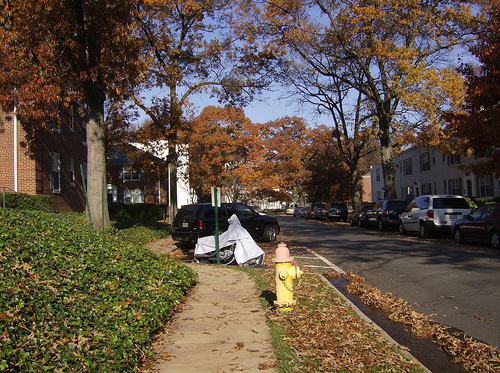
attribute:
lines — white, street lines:
[287, 235, 347, 273]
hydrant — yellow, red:
[265, 235, 311, 316]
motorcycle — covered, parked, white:
[187, 209, 274, 271]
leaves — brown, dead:
[339, 266, 499, 369]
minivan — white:
[394, 187, 477, 239]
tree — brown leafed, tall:
[5, 2, 153, 234]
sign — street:
[208, 183, 224, 212]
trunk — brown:
[82, 91, 111, 232]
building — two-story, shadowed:
[0, 80, 85, 199]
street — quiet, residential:
[301, 206, 499, 366]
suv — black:
[163, 198, 285, 243]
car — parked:
[450, 196, 499, 249]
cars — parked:
[283, 186, 497, 237]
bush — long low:
[247, 180, 304, 206]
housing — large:
[5, 83, 180, 220]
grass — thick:
[0, 213, 157, 363]